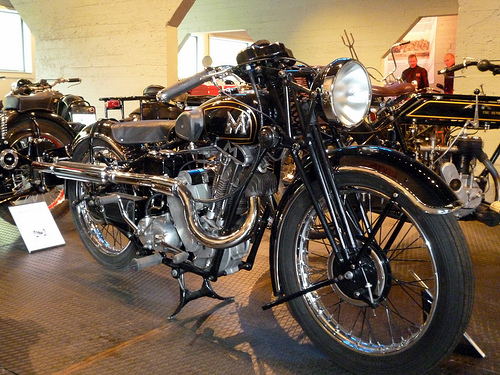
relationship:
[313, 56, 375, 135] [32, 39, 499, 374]
headlight on bike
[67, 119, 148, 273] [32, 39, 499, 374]
tire on bike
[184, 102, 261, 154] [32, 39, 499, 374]
tank on bike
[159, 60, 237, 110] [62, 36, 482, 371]
bar on motorcycle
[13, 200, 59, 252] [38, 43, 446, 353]
object beside bike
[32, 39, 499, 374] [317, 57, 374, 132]
bike has headlight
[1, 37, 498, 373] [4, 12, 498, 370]
motorcycles in building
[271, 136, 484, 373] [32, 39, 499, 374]
tire of bike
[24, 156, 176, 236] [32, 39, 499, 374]
muffler of bike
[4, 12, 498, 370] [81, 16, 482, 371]
building with motorcycles